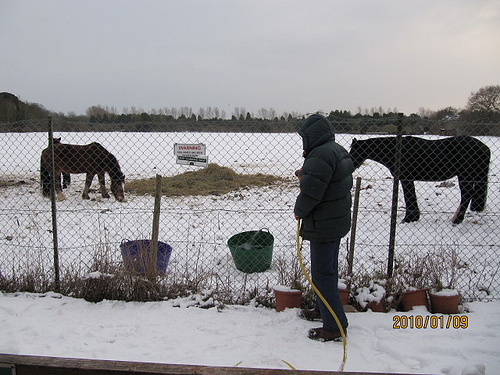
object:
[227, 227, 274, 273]
bucket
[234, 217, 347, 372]
hose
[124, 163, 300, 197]
hay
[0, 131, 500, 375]
snow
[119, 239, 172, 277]
bucket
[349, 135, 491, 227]
horse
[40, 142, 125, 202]
horse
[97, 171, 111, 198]
front leg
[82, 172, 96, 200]
front leg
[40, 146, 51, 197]
tail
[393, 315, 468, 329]
timestamp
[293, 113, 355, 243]
jacket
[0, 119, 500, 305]
wire fence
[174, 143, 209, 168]
signs/snow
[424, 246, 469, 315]
planting pot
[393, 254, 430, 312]
planting pot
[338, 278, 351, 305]
planting pot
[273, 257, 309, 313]
planting pot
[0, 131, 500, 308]
field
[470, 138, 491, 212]
tail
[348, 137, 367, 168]
head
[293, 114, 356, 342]
person